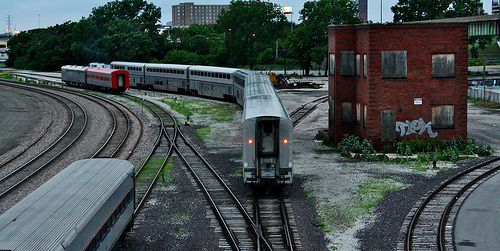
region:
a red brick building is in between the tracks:
[323, 15, 470, 155]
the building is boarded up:
[322, 21, 469, 149]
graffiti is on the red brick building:
[386, 106, 441, 141]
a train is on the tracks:
[107, 53, 297, 185]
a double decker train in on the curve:
[111, 52, 292, 192]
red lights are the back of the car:
[240, 113, 295, 198]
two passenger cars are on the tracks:
[56, 62, 128, 95]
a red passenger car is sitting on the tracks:
[85, 66, 129, 93]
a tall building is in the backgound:
[173, 2, 247, 47]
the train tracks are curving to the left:
[6, 52, 222, 247]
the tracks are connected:
[147, 102, 197, 157]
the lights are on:
[244, 133, 291, 153]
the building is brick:
[323, 12, 475, 158]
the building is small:
[315, 10, 483, 159]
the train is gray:
[135, 50, 325, 206]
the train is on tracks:
[153, 55, 349, 236]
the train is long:
[130, 60, 310, 182]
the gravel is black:
[378, 201, 400, 225]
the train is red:
[80, 62, 131, 94]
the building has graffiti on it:
[387, 116, 438, 141]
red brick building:
[318, 26, 483, 148]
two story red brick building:
[320, 17, 485, 165]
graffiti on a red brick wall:
[389, 115, 454, 135]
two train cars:
[57, 61, 132, 97]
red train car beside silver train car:
[58, 64, 133, 94]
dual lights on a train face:
[238, 114, 295, 194]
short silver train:
[109, 60, 301, 191]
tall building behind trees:
[166, 2, 249, 41]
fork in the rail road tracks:
[152, 118, 197, 157]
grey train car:
[0, 151, 144, 249]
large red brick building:
[319, 16, 476, 160]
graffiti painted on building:
[367, 90, 469, 150]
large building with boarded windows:
[317, 15, 476, 158]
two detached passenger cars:
[47, 52, 137, 99]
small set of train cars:
[98, 50, 303, 200]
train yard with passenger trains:
[3, 1, 495, 249]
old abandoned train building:
[313, 2, 498, 246]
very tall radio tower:
[1, 10, 24, 45]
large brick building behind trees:
[133, 1, 307, 45]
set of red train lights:
[236, 132, 298, 154]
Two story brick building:
[317, 27, 497, 162]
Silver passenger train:
[104, 51, 314, 200]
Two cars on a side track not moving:
[52, 56, 137, 99]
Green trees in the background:
[2, 3, 498, 85]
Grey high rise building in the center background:
[167, 1, 270, 45]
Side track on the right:
[358, 151, 498, 249]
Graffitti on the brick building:
[382, 111, 446, 147]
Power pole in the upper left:
[2, 6, 24, 44]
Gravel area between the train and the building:
[275, 87, 383, 249]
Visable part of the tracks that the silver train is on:
[230, 180, 315, 250]